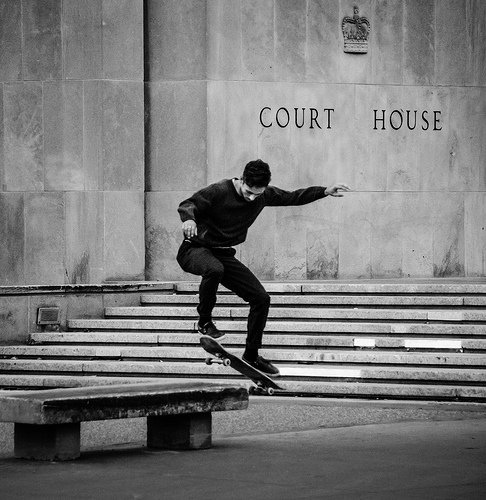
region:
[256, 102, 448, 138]
words COURT HOUSE on side of building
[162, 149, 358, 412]
man doing a trick on a skateboard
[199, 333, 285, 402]
black skateboard tilted upward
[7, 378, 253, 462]
concrete bench being used as ramp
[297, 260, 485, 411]
concrete steps leading into building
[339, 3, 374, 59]
statue of king's crown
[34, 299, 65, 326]
air vent at base of building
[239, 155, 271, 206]
thick dark hair on man's head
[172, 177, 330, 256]
black long sleeve shirt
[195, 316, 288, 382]
pair of black sneakers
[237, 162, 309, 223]
Man has dark hair.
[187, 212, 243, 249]
Man is wearing a dark shirt.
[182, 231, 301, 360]
Man has on dark pants.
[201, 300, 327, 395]
Man is wearing black and white shoes.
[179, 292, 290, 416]
Man is doing a trick on a skateboard.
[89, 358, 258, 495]
Concrete bench behind man.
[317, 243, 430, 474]
Concrete stairs near man.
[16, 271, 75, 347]
Vent in concrete wall behind man.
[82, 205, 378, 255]
Tall concrete wall behind man.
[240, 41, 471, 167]
Man is in front of the court house.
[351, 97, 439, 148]
part of some caligraph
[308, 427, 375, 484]
part of the floor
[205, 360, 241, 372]
wheels of a skateboard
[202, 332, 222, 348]
edge of a board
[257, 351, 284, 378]
part of some shoes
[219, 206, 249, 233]
part of a sweater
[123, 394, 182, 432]
edge of a bench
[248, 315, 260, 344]
part of a trouser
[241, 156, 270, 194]
hair of a man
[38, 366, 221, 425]
A weather darkened stone bench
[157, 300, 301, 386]
A man skateboards over a bench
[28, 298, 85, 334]
A vent cover hanging loose in concrete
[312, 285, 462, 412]
Stone steps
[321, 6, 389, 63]
A crown in a wall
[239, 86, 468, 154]
The words COURT HOUSE carved into a wall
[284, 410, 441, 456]
A seam in the concrete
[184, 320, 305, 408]
A skateboard in the air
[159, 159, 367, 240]
A man holds his arms for balance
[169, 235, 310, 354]
A man in dark pants with bent knees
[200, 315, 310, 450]
Man doing trick on skateboard.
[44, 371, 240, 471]
Concrete bench near man.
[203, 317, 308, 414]
Man wearing black and white shoes.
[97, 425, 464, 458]
Ground is made of concrete.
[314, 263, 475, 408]
Concrete stairs near man skateboarding.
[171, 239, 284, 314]
Man is wearing dark pants.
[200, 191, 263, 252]
Man is wearing dark shirt.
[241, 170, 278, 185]
Man has dark hair.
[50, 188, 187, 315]
Large concrete wall behind man.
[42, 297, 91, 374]
Vent in side of wall near stairs.